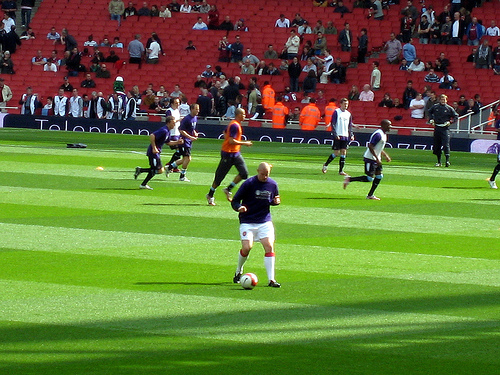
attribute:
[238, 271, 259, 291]
soccer ball — red, white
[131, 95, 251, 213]
men — running, playing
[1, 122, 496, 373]
field — green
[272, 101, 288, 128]
coat — orange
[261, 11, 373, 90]
people — watching, sitting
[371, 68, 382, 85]
shirt — white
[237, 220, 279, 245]
shorts — white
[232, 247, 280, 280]
socks — white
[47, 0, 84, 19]
seats — red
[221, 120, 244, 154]
vest — orange